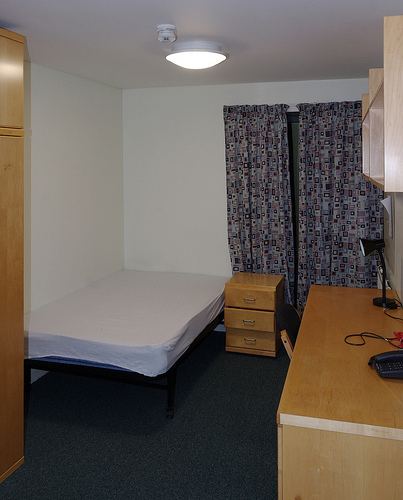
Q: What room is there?
A: Bedroom.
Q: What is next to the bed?
A: Night stand.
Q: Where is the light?
A: Ceiling.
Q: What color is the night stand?
A: Brown.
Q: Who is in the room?
A: No one.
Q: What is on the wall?
A: Shelves.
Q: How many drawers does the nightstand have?
A: Three.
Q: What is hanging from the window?
A: Curtains.